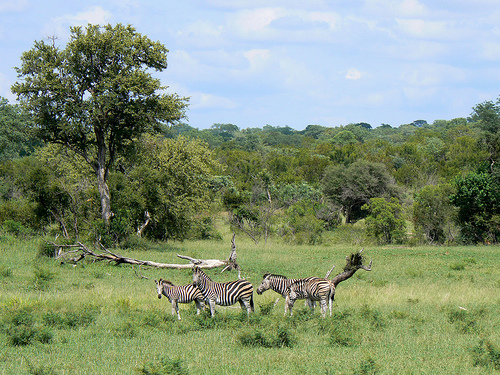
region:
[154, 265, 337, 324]
three zebras in a field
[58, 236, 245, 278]
fallen tree in a field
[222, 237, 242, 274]
roots of a fallen tree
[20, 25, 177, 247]
a large green tree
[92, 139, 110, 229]
the trunk of a tree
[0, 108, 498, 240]
a lush patch of foliage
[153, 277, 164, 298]
the head of a zebra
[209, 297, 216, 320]
front leg of a zebra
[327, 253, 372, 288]
a piece of a tree branch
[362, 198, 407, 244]
small tree in a field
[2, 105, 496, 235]
bunch of bushes and trees in the back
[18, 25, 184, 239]
large tree in the left side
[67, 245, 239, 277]
thin brown stump in the ground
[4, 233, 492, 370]
green grass where zebras are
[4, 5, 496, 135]
light blue and cloudy sky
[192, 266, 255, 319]
zebra in the middle with head up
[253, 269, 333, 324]
zebra at the right side looking the other zebra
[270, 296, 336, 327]
four thin legs from zebra in the right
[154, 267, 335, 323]
zebras are black and white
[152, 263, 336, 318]
three zebras in a green field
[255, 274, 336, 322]
black and white stripes on a zebra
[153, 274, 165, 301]
gray head of a zebra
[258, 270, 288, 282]
black mane on a black and white zebra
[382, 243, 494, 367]
green grass in a field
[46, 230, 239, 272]
fallen dead tree in a green field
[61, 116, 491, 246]
trees at the back of a green field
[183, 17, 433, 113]
blue and white cloudy sky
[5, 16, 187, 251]
tall tree with green leaves at back of field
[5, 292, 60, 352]
small bushes in a grassy field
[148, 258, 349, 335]
four zebras on grassy field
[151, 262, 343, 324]
four zebras facing left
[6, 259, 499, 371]
overgrown green grass patches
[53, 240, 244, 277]
large fallen branch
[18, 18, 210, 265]
tall green tree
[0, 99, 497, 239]
trees with different shades of green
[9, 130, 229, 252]
fallen trees behind tall tree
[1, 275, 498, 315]
patches of yellow grass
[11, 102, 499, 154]
green hills in background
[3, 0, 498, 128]
small white clouds in blue sky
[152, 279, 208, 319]
a young zebra in a field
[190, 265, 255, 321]
a zebra in a field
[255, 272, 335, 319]
a zebra in a field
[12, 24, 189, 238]
a tall flourishing tree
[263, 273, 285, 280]
mane of a zebra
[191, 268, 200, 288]
the head of a zebra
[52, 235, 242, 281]
a fallen tree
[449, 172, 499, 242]
a tree tree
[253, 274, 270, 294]
the head of a zebra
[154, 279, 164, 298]
head of a zebra